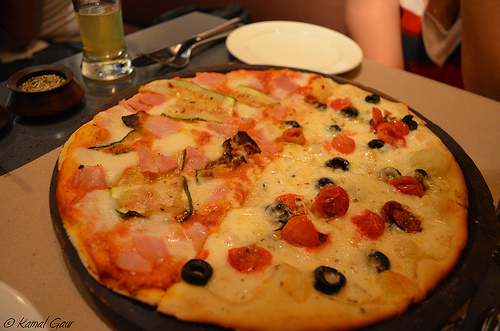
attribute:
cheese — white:
[228, 211, 273, 247]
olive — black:
[177, 256, 216, 290]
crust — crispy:
[436, 211, 477, 257]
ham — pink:
[151, 115, 178, 143]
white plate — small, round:
[218, 15, 376, 87]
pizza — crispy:
[57, 68, 464, 330]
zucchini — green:
[160, 78, 247, 136]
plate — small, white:
[0, 278, 52, 329]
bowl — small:
[5, 62, 77, 116]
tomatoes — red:
[228, 79, 427, 281]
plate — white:
[0, 284, 51, 329]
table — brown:
[352, 53, 499, 127]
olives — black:
[180, 257, 210, 284]